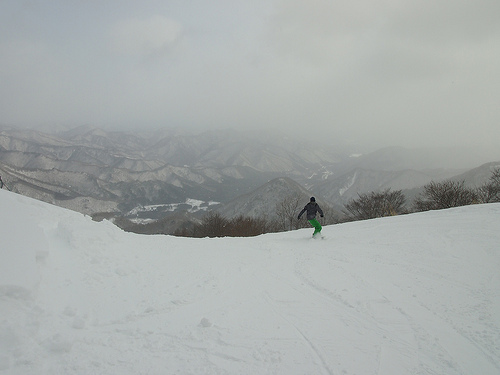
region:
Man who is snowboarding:
[286, 186, 336, 246]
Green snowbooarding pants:
[301, 216, 329, 243]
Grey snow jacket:
[296, 197, 331, 226]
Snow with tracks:
[83, 233, 287, 337]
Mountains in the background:
[25, 129, 375, 191]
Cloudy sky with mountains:
[52, 29, 343, 173]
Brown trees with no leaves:
[353, 189, 490, 239]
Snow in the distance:
[100, 171, 251, 238]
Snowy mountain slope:
[11, 159, 467, 364]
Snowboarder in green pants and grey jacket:
[279, 181, 359, 276]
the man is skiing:
[270, 175, 360, 252]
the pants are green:
[297, 213, 331, 243]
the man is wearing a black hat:
[300, 191, 322, 206]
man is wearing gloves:
[284, 208, 327, 221]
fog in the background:
[225, 116, 444, 213]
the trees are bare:
[167, 207, 264, 244]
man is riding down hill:
[194, 154, 388, 302]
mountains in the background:
[37, 104, 280, 178]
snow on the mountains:
[295, 145, 365, 195]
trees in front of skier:
[279, 181, 398, 232]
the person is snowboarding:
[278, 186, 331, 253]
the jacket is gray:
[291, 203, 331, 218]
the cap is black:
[298, 191, 323, 206]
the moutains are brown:
[66, 122, 262, 194]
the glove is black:
[289, 209, 302, 225]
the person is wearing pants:
[303, 217, 326, 243]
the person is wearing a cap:
[300, 191, 320, 202]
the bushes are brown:
[351, 173, 472, 219]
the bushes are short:
[178, 209, 264, 236]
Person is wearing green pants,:
[297, 195, 330, 240]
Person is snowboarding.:
[296, 193, 329, 240]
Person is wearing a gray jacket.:
[296, 194, 338, 240]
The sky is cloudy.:
[1, 0, 498, 133]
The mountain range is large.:
[0, 125, 499, 194]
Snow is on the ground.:
[0, 240, 499, 373]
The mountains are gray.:
[1, 133, 318, 196]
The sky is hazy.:
[0, 0, 497, 130]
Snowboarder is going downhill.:
[294, 188, 336, 241]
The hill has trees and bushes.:
[180, 172, 497, 238]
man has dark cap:
[304, 191, 315, 210]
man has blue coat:
[297, 196, 320, 211]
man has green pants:
[288, 200, 328, 235]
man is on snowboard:
[305, 223, 323, 251]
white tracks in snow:
[230, 218, 381, 372]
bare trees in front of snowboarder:
[210, 193, 455, 243]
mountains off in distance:
[28, 132, 387, 202]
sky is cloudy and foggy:
[197, 26, 490, 159]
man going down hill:
[30, 176, 440, 316]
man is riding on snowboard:
[288, 183, 348, 268]